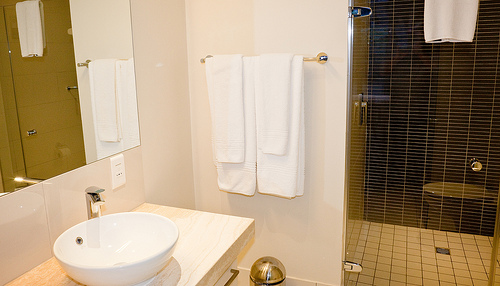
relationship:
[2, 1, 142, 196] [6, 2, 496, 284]
glass in bathroom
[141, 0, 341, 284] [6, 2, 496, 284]
walls in bathroom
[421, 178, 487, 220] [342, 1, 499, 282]
seat on glass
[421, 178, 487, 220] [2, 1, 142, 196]
seat on glass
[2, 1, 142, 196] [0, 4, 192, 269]
glass on wall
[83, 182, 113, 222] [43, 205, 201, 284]
faucet over sink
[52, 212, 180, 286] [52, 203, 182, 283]
sink over sink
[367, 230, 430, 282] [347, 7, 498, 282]
tiles on shower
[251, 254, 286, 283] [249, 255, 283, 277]
can has top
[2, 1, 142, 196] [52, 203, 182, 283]
glass over sink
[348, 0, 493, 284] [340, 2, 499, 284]
stall has door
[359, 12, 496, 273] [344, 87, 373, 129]
shower has handle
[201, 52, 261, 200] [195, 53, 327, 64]
towel on rack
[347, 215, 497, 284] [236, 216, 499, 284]
square tiles on floor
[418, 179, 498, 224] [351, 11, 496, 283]
commode behind barrier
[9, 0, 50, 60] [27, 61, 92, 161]
towel on locker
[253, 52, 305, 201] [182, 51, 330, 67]
towel on rack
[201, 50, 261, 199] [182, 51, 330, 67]
towel on rack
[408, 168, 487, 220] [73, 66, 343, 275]
seat in bathroom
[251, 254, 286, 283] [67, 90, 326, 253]
can in bathroom